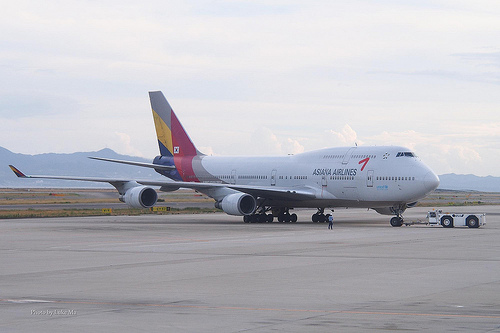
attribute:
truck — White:
[400, 206, 485, 228]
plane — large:
[10, 91, 440, 219]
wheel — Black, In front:
[384, 213, 402, 230]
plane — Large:
[5, 88, 443, 229]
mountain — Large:
[27, 142, 85, 184]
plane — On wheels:
[16, 54, 498, 261]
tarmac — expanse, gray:
[88, 223, 370, 298]